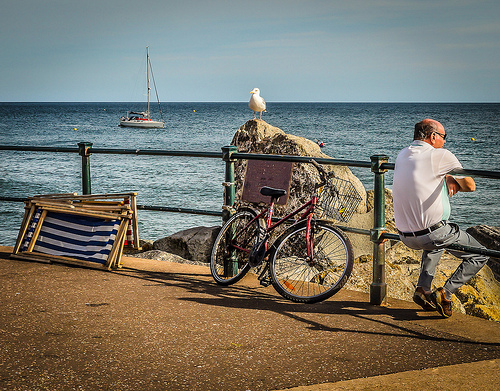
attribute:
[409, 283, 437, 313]
shoe — brown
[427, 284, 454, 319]
shoe — brown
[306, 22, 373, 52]
sky — blue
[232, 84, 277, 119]
seagull — white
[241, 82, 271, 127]
seagull — white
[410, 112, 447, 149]
head — balding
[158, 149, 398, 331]
bike — parked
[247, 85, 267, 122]
bird — white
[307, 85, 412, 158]
water — calm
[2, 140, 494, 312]
fence — metal, green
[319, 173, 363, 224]
basket — metal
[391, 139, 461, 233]
shirt — white